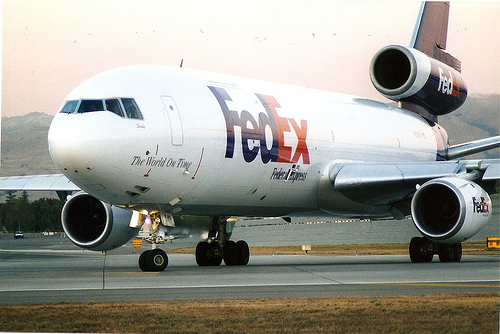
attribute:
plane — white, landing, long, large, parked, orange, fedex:
[58, 61, 466, 205]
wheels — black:
[201, 237, 251, 260]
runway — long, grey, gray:
[300, 249, 356, 282]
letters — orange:
[211, 86, 319, 166]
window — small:
[120, 99, 145, 121]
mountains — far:
[17, 108, 45, 123]